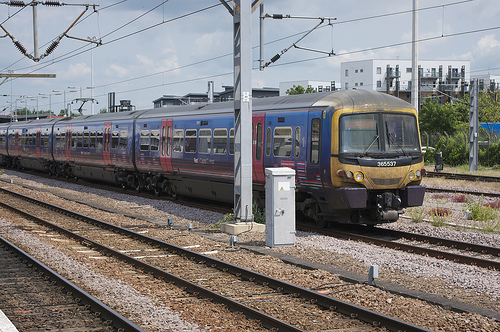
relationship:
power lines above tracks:
[258, 2, 490, 67] [14, 188, 249, 323]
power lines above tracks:
[258, 2, 490, 67] [354, 225, 481, 260]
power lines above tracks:
[3, 2, 223, 97] [14, 188, 249, 323]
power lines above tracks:
[3, 2, 223, 97] [354, 225, 481, 260]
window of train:
[336, 109, 426, 166] [125, 85, 437, 232]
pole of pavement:
[198, 17, 273, 239] [226, 217, 258, 235]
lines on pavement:
[38, 13, 189, 43] [227, 222, 272, 245]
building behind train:
[338, 59, 470, 99] [2, 87, 425, 229]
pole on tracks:
[459, 73, 482, 170] [422, 222, 484, 264]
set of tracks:
[442, 148, 485, 319] [427, 178, 498, 208]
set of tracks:
[296, 233, 446, 330] [421, 163, 497, 197]